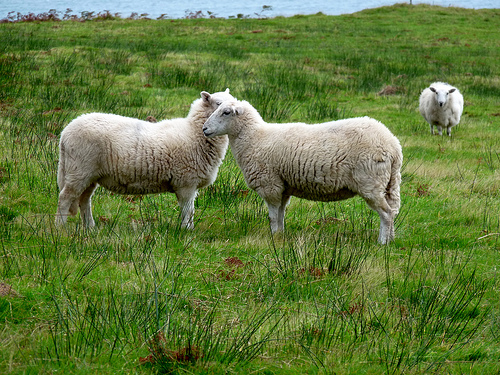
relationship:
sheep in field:
[52, 72, 412, 244] [260, 34, 359, 93]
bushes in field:
[117, 295, 206, 362] [260, 34, 359, 93]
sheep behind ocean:
[52, 72, 412, 244] [104, 1, 161, 20]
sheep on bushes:
[52, 72, 412, 244] [117, 295, 206, 362]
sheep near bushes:
[52, 72, 412, 244] [117, 295, 206, 362]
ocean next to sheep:
[104, 1, 161, 20] [52, 72, 412, 244]